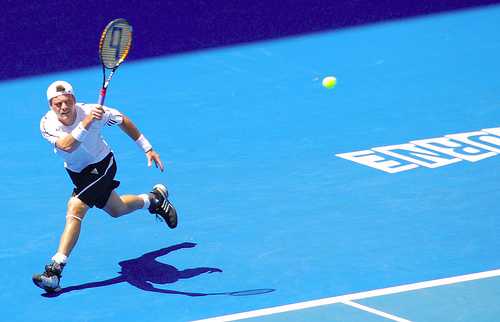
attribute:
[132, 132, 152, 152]
band — white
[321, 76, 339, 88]
ball — real, green, small, flying, yellow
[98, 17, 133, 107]
racket — real, wood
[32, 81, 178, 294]
man — playing, running, finishing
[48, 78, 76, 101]
cap — real, white, backwards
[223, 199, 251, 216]
ground — real, blue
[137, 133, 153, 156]
band — white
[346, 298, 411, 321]
line — white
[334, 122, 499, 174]
letters — blue, white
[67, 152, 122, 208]
shorts — black